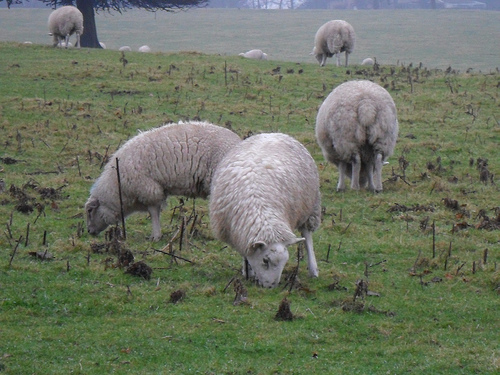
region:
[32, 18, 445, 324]
herd grazing on grass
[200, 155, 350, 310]
sheep with heads bent sideways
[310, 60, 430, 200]
woolly mound with flat tail and legs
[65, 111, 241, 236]
curved neck and back of sheep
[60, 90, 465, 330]
black stems sticking out of the ground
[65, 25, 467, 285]
lower elevation in back of the sheep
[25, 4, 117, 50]
sheep standing under a tree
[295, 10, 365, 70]
sheep eating near edge of hill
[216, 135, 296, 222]
wool in separated clumps on back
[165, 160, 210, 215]
dark wool on underside of sheep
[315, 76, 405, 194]
backside of a sheep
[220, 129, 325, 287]
sheep eating grass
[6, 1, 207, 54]
tree on the grass field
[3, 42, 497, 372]
large grass field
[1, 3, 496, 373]
five sheep visible in picture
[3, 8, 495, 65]
hill in background beyond field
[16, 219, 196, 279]
dead plants in green field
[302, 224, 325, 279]
sheep has bare white legs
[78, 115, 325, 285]
sheep has dirty white fur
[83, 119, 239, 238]
sheep fur is curly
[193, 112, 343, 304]
sheep is grazing in grass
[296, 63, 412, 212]
sheep is feeding on grass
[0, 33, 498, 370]
the grass is green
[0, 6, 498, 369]
field is large and green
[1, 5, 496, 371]
field is grass and weeds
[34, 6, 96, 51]
sheep has white wool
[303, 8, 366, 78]
sheep has white wool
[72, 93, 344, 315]
sheep are eating grass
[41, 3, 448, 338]
sheep are walking around in a large field of green grass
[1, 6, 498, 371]
grass is green and trimmed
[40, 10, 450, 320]
the animals are white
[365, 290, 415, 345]
the grass is green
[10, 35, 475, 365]
this is a farm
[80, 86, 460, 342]
the animals are feeding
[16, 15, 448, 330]
it is an outdoor scene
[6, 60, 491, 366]
it is cloudy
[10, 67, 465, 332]
it is a daytime scene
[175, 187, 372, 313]
the animal eyes are black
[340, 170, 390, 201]
shadow is cast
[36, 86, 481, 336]
the animals are facing down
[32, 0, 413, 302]
Flock of sheeps in the prairie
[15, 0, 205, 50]
Tree in the prairie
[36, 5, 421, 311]
Sheeps eating grass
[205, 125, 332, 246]
Wool in the body of sheep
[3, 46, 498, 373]
Prairie is cover with green grass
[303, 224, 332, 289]
Back leg of sheep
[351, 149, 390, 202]
Back legs of sheep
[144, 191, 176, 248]
Front legs of sheep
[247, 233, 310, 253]
Ears of sheep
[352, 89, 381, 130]
Tail of sheep is furry